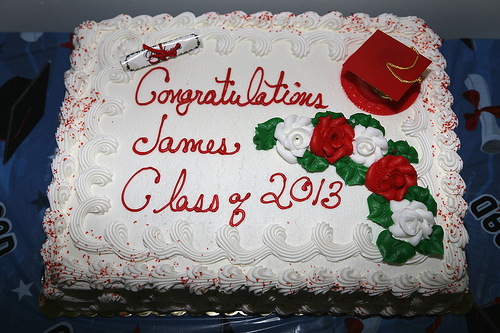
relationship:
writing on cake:
[123, 68, 354, 218] [41, 19, 476, 310]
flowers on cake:
[251, 105, 447, 267] [41, 19, 476, 310]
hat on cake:
[330, 26, 429, 142] [41, 19, 476, 310]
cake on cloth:
[41, 19, 476, 310] [1, 28, 500, 298]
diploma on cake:
[116, 31, 210, 75] [41, 19, 476, 310]